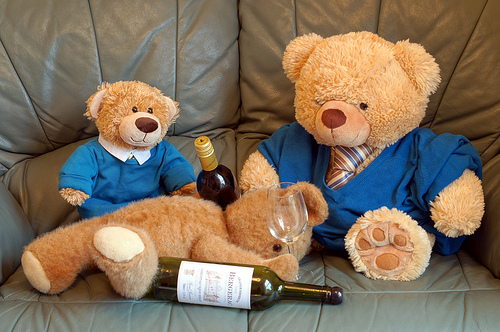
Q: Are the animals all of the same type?
A: Yes, all the animals are bears.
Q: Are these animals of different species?
A: No, all the animals are bears.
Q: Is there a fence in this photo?
A: No, there are no fences.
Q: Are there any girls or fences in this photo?
A: No, there are no fences or girls.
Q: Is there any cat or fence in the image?
A: No, there are no fences or cats.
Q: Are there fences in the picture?
A: No, there are no fences.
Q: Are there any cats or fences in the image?
A: No, there are no fences or cats.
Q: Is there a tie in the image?
A: Yes, there is a tie.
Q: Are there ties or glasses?
A: Yes, there is a tie.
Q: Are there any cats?
A: No, there are no cats.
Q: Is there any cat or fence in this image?
A: No, there are no cats or fences.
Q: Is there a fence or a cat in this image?
A: No, there are no cats or fences.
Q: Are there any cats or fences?
A: No, there are no cats or fences.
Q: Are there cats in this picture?
A: No, there are no cats.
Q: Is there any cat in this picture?
A: No, there are no cats.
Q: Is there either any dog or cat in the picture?
A: No, there are no cats or dogs.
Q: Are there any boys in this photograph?
A: No, there are no boys.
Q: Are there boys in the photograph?
A: No, there are no boys.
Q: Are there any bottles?
A: Yes, there is a bottle.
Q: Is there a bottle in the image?
A: Yes, there is a bottle.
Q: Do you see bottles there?
A: Yes, there is a bottle.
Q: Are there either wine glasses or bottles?
A: Yes, there is a bottle.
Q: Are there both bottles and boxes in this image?
A: No, there is a bottle but no boxes.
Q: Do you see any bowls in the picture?
A: No, there are no bowls.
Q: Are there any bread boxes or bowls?
A: No, there are no bowls or bread boxes.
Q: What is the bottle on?
A: The bottle is on the couch.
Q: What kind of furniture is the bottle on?
A: The bottle is on the couch.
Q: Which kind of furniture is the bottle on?
A: The bottle is on the couch.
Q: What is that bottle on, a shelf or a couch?
A: The bottle is on a couch.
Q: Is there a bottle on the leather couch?
A: Yes, there is a bottle on the couch.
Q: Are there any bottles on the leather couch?
A: Yes, there is a bottle on the couch.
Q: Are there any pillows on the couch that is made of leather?
A: No, there is a bottle on the couch.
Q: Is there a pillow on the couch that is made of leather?
A: No, there is a bottle on the couch.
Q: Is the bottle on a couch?
A: Yes, the bottle is on a couch.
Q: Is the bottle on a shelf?
A: No, the bottle is on a couch.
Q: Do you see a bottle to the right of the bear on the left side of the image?
A: Yes, there is a bottle to the right of the bear.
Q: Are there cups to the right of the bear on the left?
A: No, there is a bottle to the right of the bear.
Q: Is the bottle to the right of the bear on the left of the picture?
A: Yes, the bottle is to the right of the bear.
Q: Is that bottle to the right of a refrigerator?
A: No, the bottle is to the right of the bear.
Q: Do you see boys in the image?
A: No, there are no boys.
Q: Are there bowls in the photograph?
A: No, there are no bowls.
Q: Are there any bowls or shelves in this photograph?
A: No, there are no bowls or shelves.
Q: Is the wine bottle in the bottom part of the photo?
A: Yes, the wine bottle is in the bottom of the image.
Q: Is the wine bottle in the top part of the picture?
A: No, the wine bottle is in the bottom of the image.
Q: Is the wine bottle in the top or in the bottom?
A: The wine bottle is in the bottom of the image.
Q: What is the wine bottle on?
A: The wine bottle is on the couch.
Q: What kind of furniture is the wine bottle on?
A: The wine bottle is on the couch.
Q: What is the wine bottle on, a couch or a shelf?
A: The wine bottle is on a couch.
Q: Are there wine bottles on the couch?
A: Yes, there is a wine bottle on the couch.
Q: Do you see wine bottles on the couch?
A: Yes, there is a wine bottle on the couch.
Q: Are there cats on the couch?
A: No, there is a wine bottle on the couch.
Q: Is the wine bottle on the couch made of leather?
A: Yes, the wine bottle is on the couch.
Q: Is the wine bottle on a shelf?
A: No, the wine bottle is on the couch.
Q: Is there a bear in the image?
A: Yes, there is a bear.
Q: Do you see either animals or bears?
A: Yes, there is a bear.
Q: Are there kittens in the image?
A: No, there are no kittens.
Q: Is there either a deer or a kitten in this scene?
A: No, there are no kittens or deer.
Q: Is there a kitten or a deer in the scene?
A: No, there are no kittens or deer.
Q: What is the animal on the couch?
A: The animal is a bear.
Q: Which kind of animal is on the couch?
A: The animal is a bear.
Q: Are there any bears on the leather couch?
A: Yes, there is a bear on the couch.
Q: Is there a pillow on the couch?
A: No, there is a bear on the couch.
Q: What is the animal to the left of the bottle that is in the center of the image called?
A: The animal is a bear.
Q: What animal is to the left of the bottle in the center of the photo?
A: The animal is a bear.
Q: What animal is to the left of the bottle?
A: The animal is a bear.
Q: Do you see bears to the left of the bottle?
A: Yes, there is a bear to the left of the bottle.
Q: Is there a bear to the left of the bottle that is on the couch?
A: Yes, there is a bear to the left of the bottle.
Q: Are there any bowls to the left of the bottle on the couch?
A: No, there is a bear to the left of the bottle.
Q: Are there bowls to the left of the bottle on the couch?
A: No, there is a bear to the left of the bottle.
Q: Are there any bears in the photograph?
A: Yes, there is a bear.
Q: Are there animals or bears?
A: Yes, there is a bear.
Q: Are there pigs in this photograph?
A: No, there are no pigs.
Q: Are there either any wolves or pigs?
A: No, there are no pigs or wolves.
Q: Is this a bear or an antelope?
A: This is a bear.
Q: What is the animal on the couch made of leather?
A: The animal is a bear.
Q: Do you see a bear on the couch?
A: Yes, there is a bear on the couch.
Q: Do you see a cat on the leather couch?
A: No, there is a bear on the couch.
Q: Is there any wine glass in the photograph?
A: Yes, there is a wine glass.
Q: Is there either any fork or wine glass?
A: Yes, there is a wine glass.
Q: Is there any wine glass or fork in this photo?
A: Yes, there is a wine glass.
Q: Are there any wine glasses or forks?
A: Yes, there is a wine glass.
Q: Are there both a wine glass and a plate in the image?
A: No, there is a wine glass but no plates.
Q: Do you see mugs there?
A: No, there are no mugs.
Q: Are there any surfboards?
A: Yes, there is a surfboard.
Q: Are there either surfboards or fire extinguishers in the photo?
A: Yes, there is a surfboard.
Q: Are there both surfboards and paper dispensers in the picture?
A: No, there is a surfboard but no paper dispensers.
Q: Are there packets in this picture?
A: No, there are no packets.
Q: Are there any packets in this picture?
A: No, there are no packets.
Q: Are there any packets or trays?
A: No, there are no packets or trays.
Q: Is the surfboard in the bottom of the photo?
A: Yes, the surfboard is in the bottom of the image.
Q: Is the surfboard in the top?
A: No, the surfboard is in the bottom of the image.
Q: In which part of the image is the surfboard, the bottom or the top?
A: The surfboard is in the bottom of the image.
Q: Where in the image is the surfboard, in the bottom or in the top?
A: The surfboard is in the bottom of the image.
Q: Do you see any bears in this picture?
A: Yes, there is a bear.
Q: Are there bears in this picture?
A: Yes, there is a bear.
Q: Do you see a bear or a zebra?
A: Yes, there is a bear.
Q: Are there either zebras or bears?
A: Yes, there is a bear.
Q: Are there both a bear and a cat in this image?
A: No, there is a bear but no cats.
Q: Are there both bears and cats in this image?
A: No, there is a bear but no cats.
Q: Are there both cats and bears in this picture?
A: No, there is a bear but no cats.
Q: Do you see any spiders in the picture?
A: No, there are no spiders.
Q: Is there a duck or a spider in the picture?
A: No, there are no spiders or ducks.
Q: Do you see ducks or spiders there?
A: No, there are no spiders or ducks.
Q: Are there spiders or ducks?
A: No, there are no spiders or ducks.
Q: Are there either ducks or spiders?
A: No, there are no spiders or ducks.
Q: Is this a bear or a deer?
A: This is a bear.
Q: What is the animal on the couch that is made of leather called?
A: The animal is a bear.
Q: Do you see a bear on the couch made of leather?
A: Yes, there is a bear on the couch.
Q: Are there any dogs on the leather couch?
A: No, there is a bear on the couch.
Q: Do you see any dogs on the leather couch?
A: No, there is a bear on the couch.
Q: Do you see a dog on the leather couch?
A: No, there is a bear on the couch.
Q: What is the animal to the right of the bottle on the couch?
A: The animal is a bear.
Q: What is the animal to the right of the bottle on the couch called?
A: The animal is a bear.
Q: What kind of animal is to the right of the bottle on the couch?
A: The animal is a bear.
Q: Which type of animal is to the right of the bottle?
A: The animal is a bear.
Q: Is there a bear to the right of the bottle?
A: Yes, there is a bear to the right of the bottle.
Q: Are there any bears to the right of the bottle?
A: Yes, there is a bear to the right of the bottle.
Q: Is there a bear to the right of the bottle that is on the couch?
A: Yes, there is a bear to the right of the bottle.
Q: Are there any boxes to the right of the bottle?
A: No, there is a bear to the right of the bottle.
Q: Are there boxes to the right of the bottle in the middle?
A: No, there is a bear to the right of the bottle.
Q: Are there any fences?
A: No, there are no fences.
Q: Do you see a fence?
A: No, there are no fences.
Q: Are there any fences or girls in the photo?
A: No, there are no fences or girls.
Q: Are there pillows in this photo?
A: No, there are no pillows.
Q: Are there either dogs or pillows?
A: No, there are no pillows or dogs.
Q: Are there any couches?
A: Yes, there is a couch.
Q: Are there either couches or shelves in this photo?
A: Yes, there is a couch.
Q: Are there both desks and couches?
A: No, there is a couch but no desks.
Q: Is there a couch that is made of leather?
A: Yes, there is a couch that is made of leather.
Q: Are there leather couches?
A: Yes, there is a couch that is made of leather.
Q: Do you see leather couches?
A: Yes, there is a couch that is made of leather.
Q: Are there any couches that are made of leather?
A: Yes, there is a couch that is made of leather.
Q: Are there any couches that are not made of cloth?
A: Yes, there is a couch that is made of leather.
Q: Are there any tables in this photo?
A: No, there are no tables.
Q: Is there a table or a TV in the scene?
A: No, there are no tables or televisions.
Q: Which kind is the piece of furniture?
A: The piece of furniture is a couch.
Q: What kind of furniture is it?
A: The piece of furniture is a couch.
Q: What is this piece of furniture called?
A: That is a couch.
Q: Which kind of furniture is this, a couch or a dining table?
A: That is a couch.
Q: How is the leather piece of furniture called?
A: The piece of furniture is a couch.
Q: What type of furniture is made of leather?
A: The furniture is a couch.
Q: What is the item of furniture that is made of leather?
A: The piece of furniture is a couch.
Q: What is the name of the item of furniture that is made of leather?
A: The piece of furniture is a couch.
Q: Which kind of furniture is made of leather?
A: The furniture is a couch.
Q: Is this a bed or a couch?
A: This is a couch.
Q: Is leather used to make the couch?
A: Yes, the couch is made of leather.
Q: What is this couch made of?
A: The couch is made of leather.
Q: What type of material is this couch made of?
A: The couch is made of leather.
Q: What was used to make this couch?
A: The couch is made of leather.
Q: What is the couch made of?
A: The couch is made of leather.